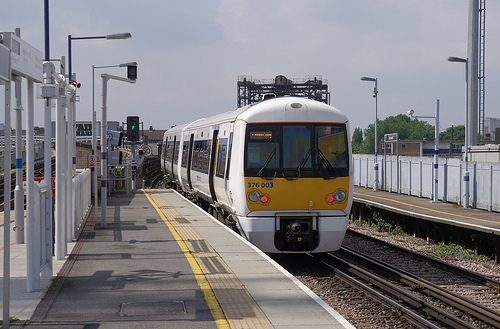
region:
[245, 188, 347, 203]
Headlights on a passenger train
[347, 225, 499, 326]
Train tracks at a train station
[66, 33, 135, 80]
Outdoor lighting for a train station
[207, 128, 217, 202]
Door on a passenger train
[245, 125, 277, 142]
Electronic sign on a passenger train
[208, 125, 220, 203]
Access door on a passenger train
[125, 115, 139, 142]
Electric light at a train station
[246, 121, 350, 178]
Windshield of a passenger train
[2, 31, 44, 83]
Sign at a train station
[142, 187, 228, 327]
Long yellow line painted on passenger area of train station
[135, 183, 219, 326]
Painted yellow line on platform.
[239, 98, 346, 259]
Yellow and white colors on front of train.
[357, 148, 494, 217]
Gray wall on side of road.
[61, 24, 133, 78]
Light pole above the ground.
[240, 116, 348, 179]
Front train windows.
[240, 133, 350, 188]
Black wipers on train windows.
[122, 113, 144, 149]
Green light on pole.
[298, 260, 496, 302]
Gravel between train tracks.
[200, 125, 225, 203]
Door on side of train.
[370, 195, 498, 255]
Brown fence beside tracks.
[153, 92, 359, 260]
White train pulling into a station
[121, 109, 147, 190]
Traffic light displaying green light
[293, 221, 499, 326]
Train tracks at train station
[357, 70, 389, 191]
Tall white lamp post next to fence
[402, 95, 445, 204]
Security camera installed on a pole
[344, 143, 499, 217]
White fence around train station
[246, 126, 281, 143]
Electronic display of train destination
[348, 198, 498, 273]
Weeds growing along underside of train palatform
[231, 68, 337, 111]
Large black industrial structure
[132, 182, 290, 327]
Yellow safety line along train platform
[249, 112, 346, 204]
yellow and white passenger train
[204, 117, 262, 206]
yellow and white passenger train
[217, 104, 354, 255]
yellow and white passenger train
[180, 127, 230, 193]
yellow and white passenger train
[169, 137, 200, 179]
yellow and white passenger train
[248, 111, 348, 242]
yellow and white light rail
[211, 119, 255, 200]
yellow and white light rail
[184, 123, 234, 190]
yellow and white light rail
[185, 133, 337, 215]
yellow and white light rail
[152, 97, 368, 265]
train white with yellow front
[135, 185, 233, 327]
long yellow line across station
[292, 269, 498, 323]
gravel laid between train tracks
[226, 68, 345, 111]
tall iron structure in background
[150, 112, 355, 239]
train doors are open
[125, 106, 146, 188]
traffic light with green light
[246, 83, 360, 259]
red lights are on on train end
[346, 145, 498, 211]
gray fence across station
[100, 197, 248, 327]
station floor made of light and dark cement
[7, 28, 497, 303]
train station has no roof